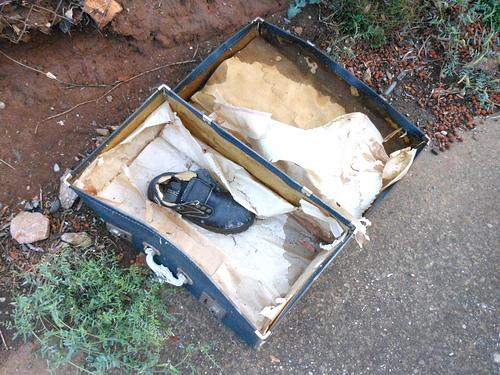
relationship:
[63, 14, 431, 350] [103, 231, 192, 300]
box has handle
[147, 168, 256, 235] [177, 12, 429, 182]
shoe in box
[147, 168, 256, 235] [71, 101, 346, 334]
shoe on paper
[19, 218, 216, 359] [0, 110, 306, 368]
vegetation on ground